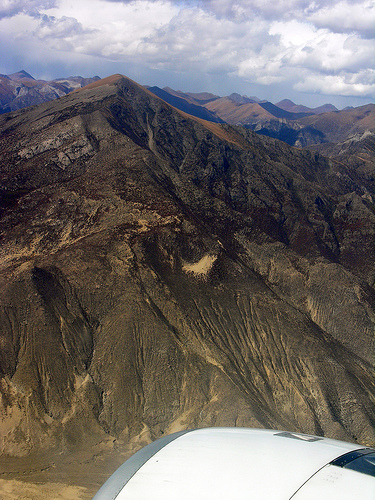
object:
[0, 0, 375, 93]
cloud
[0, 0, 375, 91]
sky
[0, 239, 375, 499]
brown mountain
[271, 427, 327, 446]
sticker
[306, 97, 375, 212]
ground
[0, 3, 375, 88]
cloudy sky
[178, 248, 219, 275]
area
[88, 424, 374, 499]
airplane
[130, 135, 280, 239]
trees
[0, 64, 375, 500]
mountain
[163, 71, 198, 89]
blue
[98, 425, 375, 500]
plane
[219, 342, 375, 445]
line